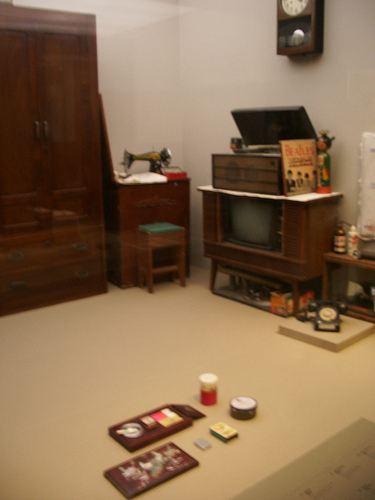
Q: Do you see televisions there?
A: Yes, there is a television.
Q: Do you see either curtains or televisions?
A: Yes, there is a television.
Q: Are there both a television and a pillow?
A: No, there is a television but no pillows.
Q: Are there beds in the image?
A: No, there are no beds.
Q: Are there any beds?
A: No, there are no beds.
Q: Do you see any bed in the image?
A: No, there are no beds.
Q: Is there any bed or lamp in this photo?
A: No, there are no beds or lamps.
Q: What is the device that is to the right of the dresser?
A: The device is a television.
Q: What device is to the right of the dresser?
A: The device is a television.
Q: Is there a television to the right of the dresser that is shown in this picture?
A: Yes, there is a television to the right of the dresser.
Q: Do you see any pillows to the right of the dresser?
A: No, there is a television to the right of the dresser.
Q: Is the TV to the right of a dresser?
A: Yes, the TV is to the right of a dresser.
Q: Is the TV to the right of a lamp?
A: No, the TV is to the right of a dresser.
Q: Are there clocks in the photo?
A: Yes, there is a clock.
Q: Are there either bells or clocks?
A: Yes, there is a clock.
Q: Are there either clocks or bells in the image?
A: Yes, there is a clock.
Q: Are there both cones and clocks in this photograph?
A: No, there is a clock but no cones.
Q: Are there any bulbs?
A: No, there are no bulbs.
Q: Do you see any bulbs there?
A: No, there are no bulbs.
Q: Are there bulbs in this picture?
A: No, there are no bulbs.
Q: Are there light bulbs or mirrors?
A: No, there are no light bulbs or mirrors.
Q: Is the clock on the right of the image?
A: Yes, the clock is on the right of the image.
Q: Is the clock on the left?
A: No, the clock is on the right of the image.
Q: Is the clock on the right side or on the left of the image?
A: The clock is on the right of the image.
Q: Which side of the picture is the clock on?
A: The clock is on the right of the image.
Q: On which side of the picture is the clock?
A: The clock is on the right of the image.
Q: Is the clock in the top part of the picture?
A: Yes, the clock is in the top of the image.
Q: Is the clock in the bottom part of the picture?
A: No, the clock is in the top of the image.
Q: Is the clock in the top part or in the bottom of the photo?
A: The clock is in the top of the image.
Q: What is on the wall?
A: The clock is on the wall.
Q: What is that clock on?
A: The clock is on the wall.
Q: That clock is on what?
A: The clock is on the wall.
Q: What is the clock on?
A: The clock is on the wall.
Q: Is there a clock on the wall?
A: Yes, there is a clock on the wall.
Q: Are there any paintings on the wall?
A: No, there is a clock on the wall.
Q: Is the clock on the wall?
A: Yes, the clock is on the wall.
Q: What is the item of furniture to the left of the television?
A: The piece of furniture is a dresser.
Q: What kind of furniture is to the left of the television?
A: The piece of furniture is a dresser.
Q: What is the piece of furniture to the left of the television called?
A: The piece of furniture is a dresser.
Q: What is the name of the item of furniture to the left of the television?
A: The piece of furniture is a dresser.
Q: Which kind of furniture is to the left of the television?
A: The piece of furniture is a dresser.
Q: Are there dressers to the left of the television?
A: Yes, there is a dresser to the left of the television.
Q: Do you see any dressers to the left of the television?
A: Yes, there is a dresser to the left of the television.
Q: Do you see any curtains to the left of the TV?
A: No, there is a dresser to the left of the TV.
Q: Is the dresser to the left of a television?
A: Yes, the dresser is to the left of a television.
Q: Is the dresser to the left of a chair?
A: No, the dresser is to the left of a television.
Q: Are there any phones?
A: Yes, there is a phone.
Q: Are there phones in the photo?
A: Yes, there is a phone.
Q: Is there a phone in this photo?
A: Yes, there is a phone.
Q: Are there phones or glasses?
A: Yes, there is a phone.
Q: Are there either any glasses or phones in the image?
A: Yes, there is a phone.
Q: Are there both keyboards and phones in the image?
A: No, there is a phone but no keyboards.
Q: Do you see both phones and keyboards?
A: No, there is a phone but no keyboards.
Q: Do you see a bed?
A: No, there are no beds.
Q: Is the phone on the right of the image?
A: Yes, the phone is on the right of the image.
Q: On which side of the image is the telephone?
A: The telephone is on the right of the image.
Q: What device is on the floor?
A: The device is a phone.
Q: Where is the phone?
A: The phone is on the floor.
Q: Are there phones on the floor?
A: Yes, there is a phone on the floor.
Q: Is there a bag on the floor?
A: No, there is a phone on the floor.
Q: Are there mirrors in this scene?
A: No, there are no mirrors.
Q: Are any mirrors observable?
A: No, there are no mirrors.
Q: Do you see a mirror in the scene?
A: No, there are no mirrors.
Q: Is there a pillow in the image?
A: No, there are no pillows.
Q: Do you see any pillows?
A: No, there are no pillows.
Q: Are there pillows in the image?
A: No, there are no pillows.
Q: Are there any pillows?
A: No, there are no pillows.